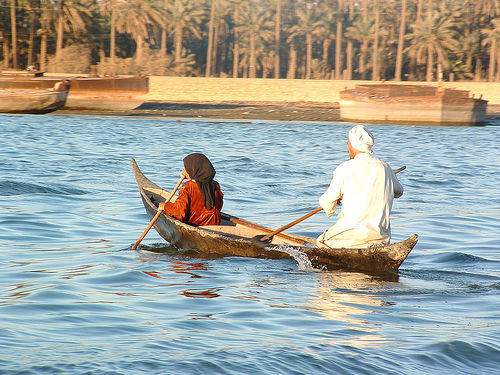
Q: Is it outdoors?
A: Yes, it is outdoors.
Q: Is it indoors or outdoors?
A: It is outdoors.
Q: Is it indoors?
A: No, it is outdoors.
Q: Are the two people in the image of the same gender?
A: No, they are both male and female.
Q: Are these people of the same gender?
A: No, they are both male and female.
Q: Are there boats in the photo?
A: Yes, there is a boat.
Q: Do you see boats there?
A: Yes, there is a boat.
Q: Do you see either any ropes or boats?
A: Yes, there is a boat.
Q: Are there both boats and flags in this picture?
A: No, there is a boat but no flags.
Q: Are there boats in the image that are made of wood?
A: Yes, there is a boat that is made of wood.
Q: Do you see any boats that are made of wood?
A: Yes, there is a boat that is made of wood.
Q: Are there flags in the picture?
A: No, there are no flags.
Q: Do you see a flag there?
A: No, there are no flags.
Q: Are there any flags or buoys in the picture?
A: No, there are no flags or buoys.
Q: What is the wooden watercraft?
A: The watercraft is a boat.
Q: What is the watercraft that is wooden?
A: The watercraft is a boat.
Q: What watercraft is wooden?
A: The watercraft is a boat.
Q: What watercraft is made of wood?
A: The watercraft is a boat.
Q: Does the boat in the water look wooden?
A: Yes, the boat is wooden.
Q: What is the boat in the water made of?
A: The boat is made of wood.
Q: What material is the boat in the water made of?
A: The boat is made of wood.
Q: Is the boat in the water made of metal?
A: No, the boat is made of wood.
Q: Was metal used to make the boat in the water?
A: No, the boat is made of wood.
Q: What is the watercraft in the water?
A: The watercraft is a boat.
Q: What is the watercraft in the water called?
A: The watercraft is a boat.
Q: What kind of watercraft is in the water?
A: The watercraft is a boat.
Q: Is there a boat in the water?
A: Yes, there is a boat in the water.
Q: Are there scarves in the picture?
A: Yes, there is a scarf.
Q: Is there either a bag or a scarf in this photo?
A: Yes, there is a scarf.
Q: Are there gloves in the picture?
A: No, there are no gloves.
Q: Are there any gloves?
A: No, there are no gloves.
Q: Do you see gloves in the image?
A: No, there are no gloves.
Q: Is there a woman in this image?
A: Yes, there is a woman.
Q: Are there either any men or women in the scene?
A: Yes, there is a woman.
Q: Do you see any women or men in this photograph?
A: Yes, there is a woman.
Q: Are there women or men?
A: Yes, there is a woman.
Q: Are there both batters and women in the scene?
A: No, there is a woman but no batters.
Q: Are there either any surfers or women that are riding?
A: Yes, the woman is riding.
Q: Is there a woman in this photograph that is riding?
A: Yes, there is a woman that is riding.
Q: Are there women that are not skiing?
A: Yes, there is a woman that is riding.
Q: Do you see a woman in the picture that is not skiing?
A: Yes, there is a woman that is riding .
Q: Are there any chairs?
A: No, there are no chairs.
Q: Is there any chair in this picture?
A: No, there are no chairs.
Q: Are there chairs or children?
A: No, there are no chairs or children.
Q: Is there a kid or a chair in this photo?
A: No, there are no chairs or children.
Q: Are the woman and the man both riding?
A: Yes, both the woman and the man are riding.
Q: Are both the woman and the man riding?
A: Yes, both the woman and the man are riding.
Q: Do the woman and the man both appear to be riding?
A: Yes, both the woman and the man are riding.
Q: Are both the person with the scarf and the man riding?
A: Yes, both the woman and the man are riding.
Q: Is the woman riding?
A: Yes, the woman is riding.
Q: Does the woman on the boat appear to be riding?
A: Yes, the woman is riding.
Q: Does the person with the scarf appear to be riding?
A: Yes, the woman is riding.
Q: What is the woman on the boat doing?
A: The woman is riding.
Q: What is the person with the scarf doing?
A: The woman is riding.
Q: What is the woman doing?
A: The woman is riding.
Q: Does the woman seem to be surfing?
A: No, the woman is riding.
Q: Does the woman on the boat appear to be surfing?
A: No, the woman is riding.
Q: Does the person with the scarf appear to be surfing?
A: No, the woman is riding.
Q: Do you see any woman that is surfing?
A: No, there is a woman but she is riding.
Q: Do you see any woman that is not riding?
A: No, there is a woman but she is riding.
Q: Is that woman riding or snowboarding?
A: The woman is riding.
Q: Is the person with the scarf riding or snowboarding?
A: The woman is riding.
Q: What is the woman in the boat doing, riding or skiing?
A: The woman is riding.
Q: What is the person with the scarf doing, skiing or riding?
A: The woman is riding.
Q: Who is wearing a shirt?
A: The woman is wearing a shirt.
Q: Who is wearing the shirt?
A: The woman is wearing a shirt.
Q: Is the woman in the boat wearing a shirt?
A: Yes, the woman is wearing a shirt.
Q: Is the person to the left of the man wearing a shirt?
A: Yes, the woman is wearing a shirt.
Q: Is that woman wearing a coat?
A: No, the woman is wearing a shirt.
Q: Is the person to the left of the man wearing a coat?
A: No, the woman is wearing a shirt.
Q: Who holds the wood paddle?
A: The woman holds the paddle.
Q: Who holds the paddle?
A: The woman holds the paddle.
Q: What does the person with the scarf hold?
A: The woman holds the paddle.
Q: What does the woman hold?
A: The woman holds the paddle.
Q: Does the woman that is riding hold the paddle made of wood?
A: Yes, the woman holds the oar.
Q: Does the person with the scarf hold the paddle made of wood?
A: Yes, the woman holds the oar.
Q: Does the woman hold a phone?
A: No, the woman holds the oar.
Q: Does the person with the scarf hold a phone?
A: No, the woman holds the oar.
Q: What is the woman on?
A: The woman is on the boat.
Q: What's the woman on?
A: The woman is on the boat.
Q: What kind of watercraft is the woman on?
A: The woman is on the boat.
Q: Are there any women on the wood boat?
A: Yes, there is a woman on the boat.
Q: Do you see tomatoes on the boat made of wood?
A: No, there is a woman on the boat.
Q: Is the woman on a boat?
A: Yes, the woman is on a boat.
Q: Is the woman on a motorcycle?
A: No, the woman is on a boat.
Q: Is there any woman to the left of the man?
A: Yes, there is a woman to the left of the man.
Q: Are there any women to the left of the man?
A: Yes, there is a woman to the left of the man.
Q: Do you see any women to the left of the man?
A: Yes, there is a woman to the left of the man.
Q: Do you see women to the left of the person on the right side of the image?
A: Yes, there is a woman to the left of the man.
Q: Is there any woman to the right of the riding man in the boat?
A: No, the woman is to the left of the man.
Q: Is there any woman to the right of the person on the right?
A: No, the woman is to the left of the man.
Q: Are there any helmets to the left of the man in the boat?
A: No, there is a woman to the left of the man.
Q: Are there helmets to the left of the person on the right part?
A: No, there is a woman to the left of the man.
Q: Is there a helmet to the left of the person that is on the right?
A: No, there is a woman to the left of the man.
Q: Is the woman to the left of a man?
A: Yes, the woman is to the left of a man.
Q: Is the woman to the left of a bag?
A: No, the woman is to the left of a man.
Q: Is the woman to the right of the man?
A: No, the woman is to the left of the man.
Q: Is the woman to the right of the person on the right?
A: No, the woman is to the left of the man.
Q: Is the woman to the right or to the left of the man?
A: The woman is to the left of the man.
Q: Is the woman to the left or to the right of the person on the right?
A: The woman is to the left of the man.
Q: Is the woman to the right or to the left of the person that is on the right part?
A: The woman is to the left of the man.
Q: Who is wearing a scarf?
A: The woman is wearing a scarf.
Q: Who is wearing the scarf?
A: The woman is wearing a scarf.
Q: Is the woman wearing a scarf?
A: Yes, the woman is wearing a scarf.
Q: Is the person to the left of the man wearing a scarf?
A: Yes, the woman is wearing a scarf.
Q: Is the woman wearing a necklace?
A: No, the woman is wearing a scarf.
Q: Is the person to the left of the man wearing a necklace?
A: No, the woman is wearing a scarf.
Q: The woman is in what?
A: The woman is in the boat.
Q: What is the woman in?
A: The woman is in the boat.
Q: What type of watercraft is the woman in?
A: The woman is in the boat.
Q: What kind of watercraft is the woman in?
A: The woman is in the boat.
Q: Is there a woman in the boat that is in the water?
A: Yes, there is a woman in the boat.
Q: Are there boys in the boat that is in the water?
A: No, there is a woman in the boat.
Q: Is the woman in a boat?
A: Yes, the woman is in a boat.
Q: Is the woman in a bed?
A: No, the woman is in a boat.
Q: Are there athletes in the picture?
A: No, there are no athletes.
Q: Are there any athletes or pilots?
A: No, there are no athletes or pilots.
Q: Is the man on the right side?
A: Yes, the man is on the right of the image.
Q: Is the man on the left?
A: No, the man is on the right of the image.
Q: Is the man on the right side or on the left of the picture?
A: The man is on the right of the image.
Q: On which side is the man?
A: The man is on the right of the image.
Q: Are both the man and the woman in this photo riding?
A: Yes, both the man and the woman are riding.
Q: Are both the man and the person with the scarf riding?
A: Yes, both the man and the woman are riding.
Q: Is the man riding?
A: Yes, the man is riding.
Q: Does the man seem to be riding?
A: Yes, the man is riding.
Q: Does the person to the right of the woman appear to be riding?
A: Yes, the man is riding.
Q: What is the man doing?
A: The man is riding.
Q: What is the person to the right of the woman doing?
A: The man is riding.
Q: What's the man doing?
A: The man is riding.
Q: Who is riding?
A: The man is riding.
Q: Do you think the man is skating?
A: No, the man is riding.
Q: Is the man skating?
A: No, the man is riding.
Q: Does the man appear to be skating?
A: No, the man is riding.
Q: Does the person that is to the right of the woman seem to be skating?
A: No, the man is riding.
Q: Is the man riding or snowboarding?
A: The man is riding.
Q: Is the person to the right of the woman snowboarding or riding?
A: The man is riding.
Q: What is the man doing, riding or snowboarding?
A: The man is riding.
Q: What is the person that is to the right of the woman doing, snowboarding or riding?
A: The man is riding.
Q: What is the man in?
A: The man is in the boat.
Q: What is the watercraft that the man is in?
A: The watercraft is a boat.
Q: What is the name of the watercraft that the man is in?
A: The watercraft is a boat.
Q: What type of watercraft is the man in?
A: The man is in the boat.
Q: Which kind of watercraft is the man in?
A: The man is in the boat.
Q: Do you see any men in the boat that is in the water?
A: Yes, there is a man in the boat.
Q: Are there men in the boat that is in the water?
A: Yes, there is a man in the boat.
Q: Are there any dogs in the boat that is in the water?
A: No, there is a man in the boat.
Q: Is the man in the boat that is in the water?
A: Yes, the man is in the boat.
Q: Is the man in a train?
A: No, the man is in the boat.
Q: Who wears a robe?
A: The man wears a robe.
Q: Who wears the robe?
A: The man wears a robe.